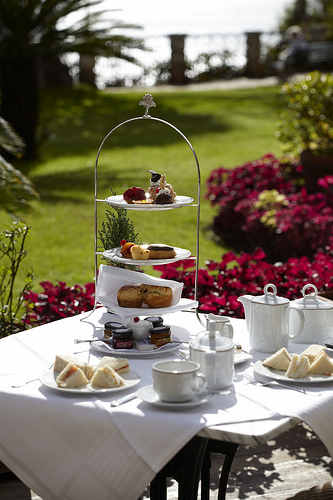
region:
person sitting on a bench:
[266, 25, 332, 83]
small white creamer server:
[203, 311, 233, 337]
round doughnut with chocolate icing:
[147, 242, 176, 258]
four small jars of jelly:
[102, 316, 171, 349]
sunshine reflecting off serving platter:
[143, 190, 151, 199]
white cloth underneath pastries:
[94, 263, 183, 318]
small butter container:
[133, 338, 154, 351]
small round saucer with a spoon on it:
[136, 384, 230, 408]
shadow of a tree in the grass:
[30, 163, 148, 206]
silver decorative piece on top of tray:
[137, 91, 156, 118]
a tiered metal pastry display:
[94, 93, 202, 355]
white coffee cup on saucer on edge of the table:
[134, 359, 211, 407]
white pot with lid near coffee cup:
[187, 317, 235, 389]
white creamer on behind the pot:
[204, 312, 252, 364]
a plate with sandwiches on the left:
[41, 356, 139, 393]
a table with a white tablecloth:
[0, 305, 332, 499]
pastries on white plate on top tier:
[107, 170, 195, 211]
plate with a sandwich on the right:
[255, 348, 332, 385]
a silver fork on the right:
[243, 372, 305, 392]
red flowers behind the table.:
[20, 150, 332, 316]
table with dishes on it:
[4, 275, 319, 491]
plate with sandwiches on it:
[262, 333, 327, 376]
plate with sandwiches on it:
[40, 355, 140, 394]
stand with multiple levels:
[81, 132, 210, 326]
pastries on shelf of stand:
[116, 284, 193, 301]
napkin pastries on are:
[94, 263, 182, 312]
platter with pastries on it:
[101, 231, 197, 269]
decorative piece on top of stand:
[132, 94, 159, 123]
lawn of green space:
[33, 100, 246, 250]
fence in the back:
[133, 23, 273, 76]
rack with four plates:
[92, 114, 200, 356]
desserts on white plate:
[108, 168, 193, 208]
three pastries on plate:
[102, 240, 189, 263]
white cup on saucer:
[137, 358, 211, 409]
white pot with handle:
[237, 280, 305, 353]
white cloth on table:
[1, 297, 331, 497]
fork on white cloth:
[241, 370, 320, 397]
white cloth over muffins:
[94, 267, 194, 319]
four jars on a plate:
[89, 315, 188, 355]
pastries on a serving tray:
[92, 92, 200, 356]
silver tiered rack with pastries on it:
[79, 114, 207, 352]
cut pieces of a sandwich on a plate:
[41, 355, 140, 391]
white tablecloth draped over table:
[0, 308, 332, 499]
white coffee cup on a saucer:
[136, 359, 214, 411]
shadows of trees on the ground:
[142, 422, 332, 499]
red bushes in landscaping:
[20, 150, 332, 319]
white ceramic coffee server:
[235, 281, 303, 355]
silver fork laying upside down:
[261, 379, 305, 395]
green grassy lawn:
[1, 84, 297, 287]